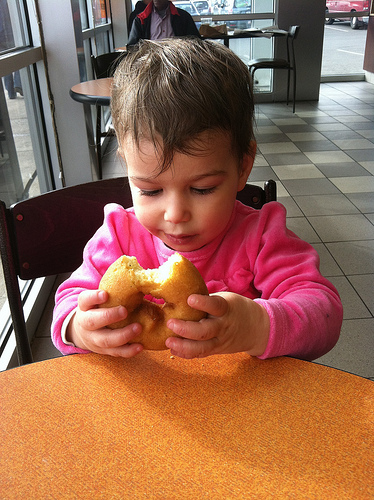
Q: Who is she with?
A: No one.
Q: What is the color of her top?
A: Pink.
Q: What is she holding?
A: Donut.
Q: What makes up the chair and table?
A: Wood.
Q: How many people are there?
A: 2.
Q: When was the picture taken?
A: During the day.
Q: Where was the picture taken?
A: In a restaurant.